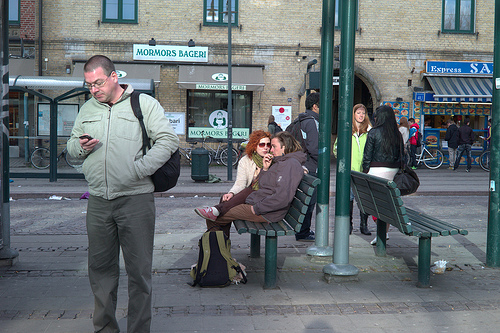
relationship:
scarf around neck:
[249, 152, 266, 169] [257, 147, 264, 153]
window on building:
[178, 81, 258, 151] [7, 5, 497, 163]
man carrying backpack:
[64, 54, 181, 333] [389, 161, 436, 202]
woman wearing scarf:
[196, 129, 273, 224] [238, 148, 264, 168]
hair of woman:
[242, 126, 265, 149] [196, 129, 273, 224]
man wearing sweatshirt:
[216, 130, 311, 271] [254, 149, 300, 225]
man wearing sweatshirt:
[205, 131, 310, 237] [255, 150, 310, 214]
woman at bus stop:
[363, 104, 404, 250] [207, 1, 467, 281]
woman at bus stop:
[343, 99, 375, 177] [207, 1, 467, 281]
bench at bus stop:
[348, 169, 470, 289] [41, 58, 496, 328]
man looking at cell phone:
[64, 54, 181, 333] [78, 135, 91, 140]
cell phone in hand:
[78, 135, 91, 140] [77, 134, 99, 152]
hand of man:
[77, 134, 99, 152] [64, 54, 181, 333]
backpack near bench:
[187, 227, 248, 289] [237, 167, 339, 247]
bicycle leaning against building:
[179, 129, 241, 167] [7, 5, 497, 163]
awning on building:
[426, 76, 492, 97] [7, 5, 497, 163]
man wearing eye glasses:
[58, 54, 171, 331] [76, 74, 114, 92]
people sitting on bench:
[201, 124, 298, 235] [217, 172, 334, 288]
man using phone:
[64, 54, 181, 333] [76, 132, 93, 142]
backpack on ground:
[187, 227, 248, 289] [0, 161, 499, 329]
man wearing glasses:
[64, 54, 181, 333] [82, 76, 109, 90]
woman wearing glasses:
[193, 129, 273, 225] [257, 142, 271, 148]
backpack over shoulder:
[144, 138, 187, 195] [117, 85, 153, 115]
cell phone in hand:
[79, 135, 93, 141] [79, 134, 100, 152]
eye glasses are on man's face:
[82, 69, 115, 90] [73, 64, 118, 106]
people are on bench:
[193, 125, 308, 238] [235, 165, 325, 290]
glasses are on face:
[256, 142, 269, 147] [255, 136, 270, 157]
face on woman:
[255, 136, 270, 157] [193, 129, 273, 225]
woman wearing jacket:
[362, 104, 421, 244] [358, 125, 404, 167]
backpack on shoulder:
[393, 153, 420, 197] [363, 122, 414, 140]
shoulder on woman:
[363, 122, 414, 140] [358, 95, 423, 201]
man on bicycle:
[410, 116, 422, 172] [408, 137, 442, 172]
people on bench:
[193, 125, 308, 238] [232, 177, 324, 284]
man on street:
[64, 54, 181, 333] [3, 184, 499, 231]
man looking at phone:
[64, 54, 181, 333] [79, 133, 95, 141]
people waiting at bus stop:
[193, 125, 308, 238] [58, 14, 482, 329]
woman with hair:
[193, 129, 273, 225] [244, 131, 259, 153]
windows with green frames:
[92, 4, 257, 35] [412, 7, 482, 56]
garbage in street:
[40, 191, 67, 212] [20, 178, 113, 249]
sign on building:
[131, 45, 211, 61] [7, 5, 497, 163]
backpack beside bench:
[187, 227, 248, 289] [210, 169, 330, 298]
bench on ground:
[235, 165, 325, 290] [0, 161, 499, 329]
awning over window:
[422, 77, 492, 97] [422, 113, 485, 129]